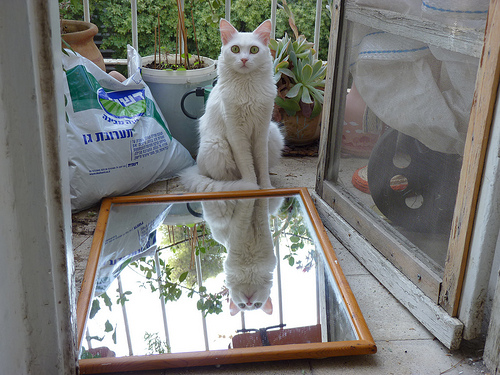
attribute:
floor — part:
[67, 153, 486, 373]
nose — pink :
[237, 56, 250, 65]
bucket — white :
[138, 53, 220, 161]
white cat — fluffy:
[186, 13, 299, 193]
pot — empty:
[60, 21, 133, 95]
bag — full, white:
[60, 37, 186, 219]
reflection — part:
[320, 44, 464, 266]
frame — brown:
[296, 189, 356, 242]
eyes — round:
[227, 30, 258, 63]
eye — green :
[248, 42, 259, 54]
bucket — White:
[138, 46, 221, 156]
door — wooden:
[28, 0, 476, 352]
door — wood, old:
[327, 3, 492, 356]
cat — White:
[186, 17, 283, 187]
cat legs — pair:
[220, 113, 287, 189]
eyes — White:
[229, 43, 260, 57]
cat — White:
[171, 15, 293, 197]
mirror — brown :
[58, 150, 352, 366]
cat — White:
[175, 16, 285, 193]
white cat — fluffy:
[189, 13, 292, 189]